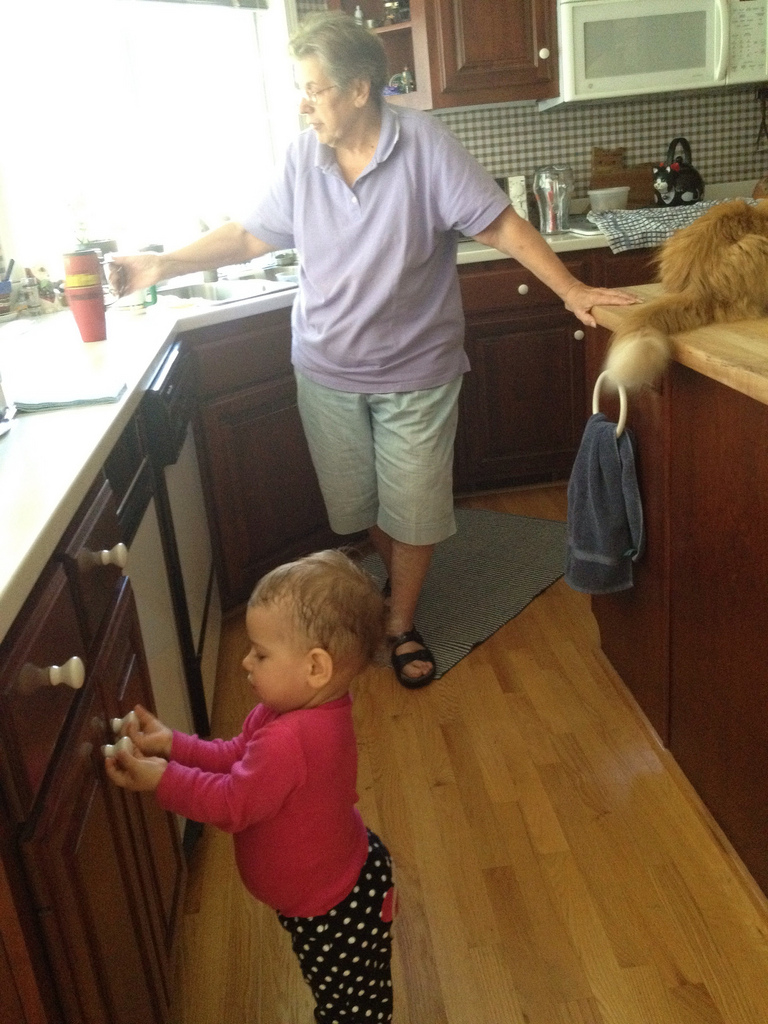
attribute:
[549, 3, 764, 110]
microwave — white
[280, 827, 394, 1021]
pants — black, white, polka dots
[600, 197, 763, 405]
cat — orange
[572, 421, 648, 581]
rug — rectangular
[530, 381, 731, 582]
towel — blue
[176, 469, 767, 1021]
floor — brown, light, hardwood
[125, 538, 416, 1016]
child — small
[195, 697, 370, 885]
shirt — red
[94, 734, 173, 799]
hand — both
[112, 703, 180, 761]
hand — both